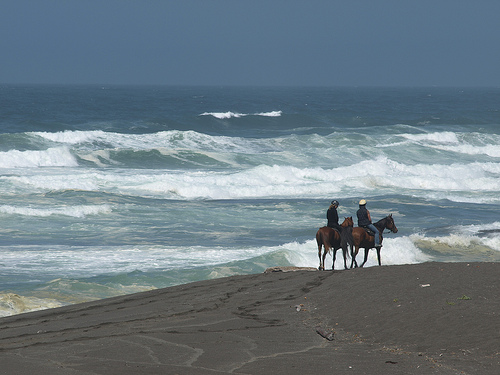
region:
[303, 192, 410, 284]
a pair of brown horses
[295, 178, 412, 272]
people horse back riding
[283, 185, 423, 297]
a pair of horses on the beach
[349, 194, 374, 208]
a white riding helmet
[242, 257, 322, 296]
some hoof prints in the sand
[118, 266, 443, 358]
a dark sandy beach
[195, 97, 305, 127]
a distant wave breaking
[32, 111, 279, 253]
a few ocean waves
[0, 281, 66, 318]
some dirty ocean foam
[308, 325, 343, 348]
a stick on the beach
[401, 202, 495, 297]
waves breaking on the shore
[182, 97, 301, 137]
crest of wave in the ocean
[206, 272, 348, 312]
foot prints left by horses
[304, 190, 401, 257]
people on horses backs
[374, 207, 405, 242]
horse head in front of ocean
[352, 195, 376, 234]
rider sitting on horse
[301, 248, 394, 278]
horses legs walking in sand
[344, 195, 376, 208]
helmet on riders head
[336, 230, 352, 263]
tail on the horse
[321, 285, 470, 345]
sand on the beach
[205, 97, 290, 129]
a white capped wave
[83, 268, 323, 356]
sea weed on the sand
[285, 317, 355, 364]
a small piece of drift wood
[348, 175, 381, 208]
white and black riding hat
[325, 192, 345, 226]
wonan wearing a black shirt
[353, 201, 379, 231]
person wearing a blue shirt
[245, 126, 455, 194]
large white capped waves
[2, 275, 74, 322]
brownish white water and froth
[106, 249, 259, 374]
sand by the water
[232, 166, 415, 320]
two horses by the beach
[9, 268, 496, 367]
black sand on beach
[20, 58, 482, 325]
ocean with large waves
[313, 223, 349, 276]
brown horse walking along sand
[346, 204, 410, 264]
brown horse walking along sand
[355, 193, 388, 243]
person on horse with a helmet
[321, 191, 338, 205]
person on horse with a helmet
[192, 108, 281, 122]
white crest of wave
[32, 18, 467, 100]
blue stormy skies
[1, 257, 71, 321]
sand upturned in rough water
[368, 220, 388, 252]
denim jeans on horse rider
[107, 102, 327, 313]
the waves are big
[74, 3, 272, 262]
the waves are big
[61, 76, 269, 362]
the waves are big